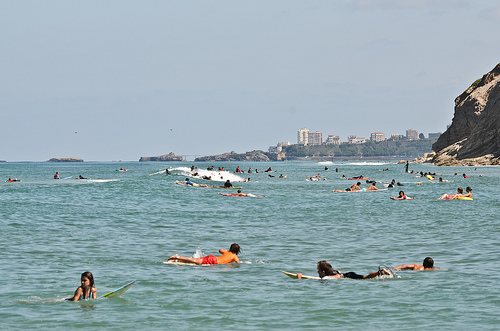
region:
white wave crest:
[156, 165, 243, 182]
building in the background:
[298, 123, 443, 146]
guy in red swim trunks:
[166, 237, 244, 267]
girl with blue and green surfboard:
[53, 269, 135, 301]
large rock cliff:
[419, 62, 499, 164]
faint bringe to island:
[178, 150, 205, 162]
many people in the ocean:
[38, 148, 482, 208]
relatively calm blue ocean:
[0, 160, 499, 329]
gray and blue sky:
[0, 1, 499, 161]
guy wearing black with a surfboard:
[283, 260, 393, 286]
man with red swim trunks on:
[165, 242, 250, 271]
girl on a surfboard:
[57, 262, 145, 309]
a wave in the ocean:
[72, 176, 124, 191]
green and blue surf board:
[102, 279, 142, 298]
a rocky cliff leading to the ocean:
[439, 85, 498, 168]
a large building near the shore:
[292, 119, 324, 151]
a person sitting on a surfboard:
[48, 167, 65, 182]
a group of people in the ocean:
[152, 156, 298, 204]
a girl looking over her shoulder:
[61, 270, 103, 307]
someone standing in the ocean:
[401, 152, 412, 177]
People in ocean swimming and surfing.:
[58, 214, 468, 319]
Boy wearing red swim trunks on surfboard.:
[161, 242, 261, 273]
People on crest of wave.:
[169, 162, 254, 186]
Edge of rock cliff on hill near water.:
[431, 61, 498, 166]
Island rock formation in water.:
[40, 153, 90, 166]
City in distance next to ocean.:
[291, 120, 443, 154]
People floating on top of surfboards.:
[329, 174, 418, 209]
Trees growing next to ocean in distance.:
[294, 138, 431, 157]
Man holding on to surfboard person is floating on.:
[281, 257, 401, 285]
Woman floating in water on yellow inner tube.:
[454, 184, 486, 206]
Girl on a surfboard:
[32, 262, 148, 318]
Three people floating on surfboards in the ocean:
[25, 232, 397, 320]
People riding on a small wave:
[162, 157, 247, 193]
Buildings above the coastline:
[198, 122, 422, 167]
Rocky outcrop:
[375, 64, 495, 168]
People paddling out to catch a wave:
[157, 174, 259, 206]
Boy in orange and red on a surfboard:
[148, 235, 250, 278]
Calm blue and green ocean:
[2, 182, 144, 264]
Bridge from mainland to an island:
[167, 150, 221, 170]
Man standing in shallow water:
[399, 155, 415, 177]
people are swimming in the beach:
[59, 151, 335, 322]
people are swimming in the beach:
[84, 212, 215, 312]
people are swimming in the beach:
[142, 183, 294, 316]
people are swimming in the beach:
[165, 202, 245, 299]